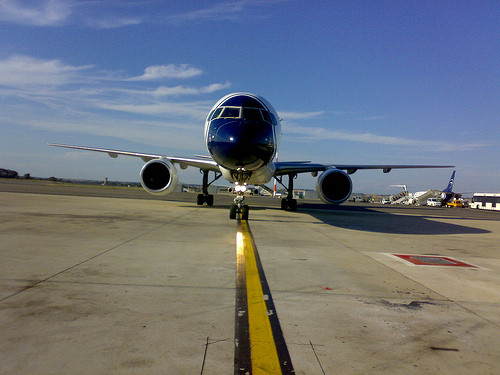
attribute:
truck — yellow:
[441, 199, 463, 211]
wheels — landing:
[208, 198, 267, 228]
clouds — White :
[1, 0, 498, 189]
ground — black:
[377, 175, 416, 213]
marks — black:
[367, 289, 441, 321]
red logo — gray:
[378, 240, 467, 295]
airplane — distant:
[407, 169, 465, 205]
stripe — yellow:
[236, 223, 279, 373]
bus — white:
[468, 192, 498, 210]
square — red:
[389, 253, 473, 268]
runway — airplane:
[40, 194, 464, 368]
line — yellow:
[220, 198, 308, 368]